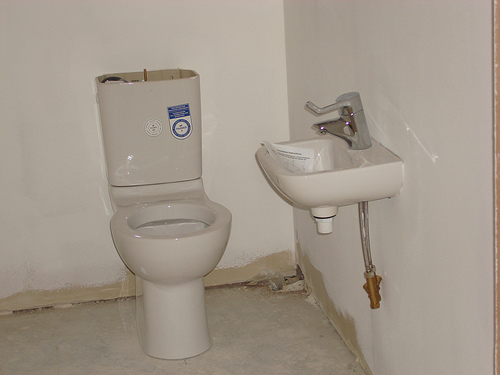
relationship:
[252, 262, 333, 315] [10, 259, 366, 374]
water damage on ground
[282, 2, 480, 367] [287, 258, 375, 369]
wall has a crack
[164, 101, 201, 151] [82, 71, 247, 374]
label on toilet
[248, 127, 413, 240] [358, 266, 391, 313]
sink has copper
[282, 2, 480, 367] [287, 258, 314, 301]
wall has scrape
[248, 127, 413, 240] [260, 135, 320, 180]
sink has paper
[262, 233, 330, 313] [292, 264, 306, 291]
corner has crack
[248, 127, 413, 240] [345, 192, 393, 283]
sink has a pipe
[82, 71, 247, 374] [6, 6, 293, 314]
toilet against wall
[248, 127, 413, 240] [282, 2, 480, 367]
sink on wall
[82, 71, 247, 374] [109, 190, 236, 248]
toilet with no lid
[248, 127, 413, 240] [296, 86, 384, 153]
sink has faucet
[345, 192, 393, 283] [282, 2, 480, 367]
pipes on wall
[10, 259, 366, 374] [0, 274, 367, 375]
damage on ground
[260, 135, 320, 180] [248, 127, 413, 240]
paper in sink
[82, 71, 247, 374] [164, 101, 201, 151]
toilet has label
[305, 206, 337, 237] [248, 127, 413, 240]
bottom drain on sink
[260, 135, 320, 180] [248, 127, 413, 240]
information in sink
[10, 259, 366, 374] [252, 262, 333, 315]
ground has water damage